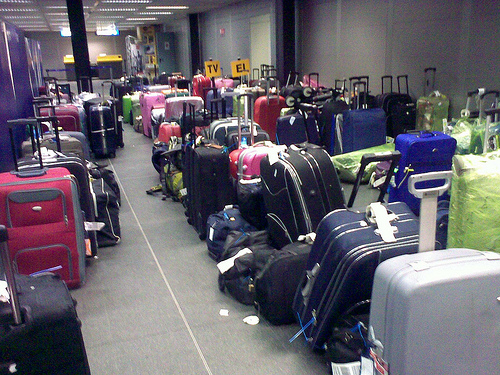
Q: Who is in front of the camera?
A: No one.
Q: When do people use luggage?
A: When they travel.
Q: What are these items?
A: Luggage.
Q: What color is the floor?
A: Gray.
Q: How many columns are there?
A: Three.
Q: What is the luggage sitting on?
A: The floor.